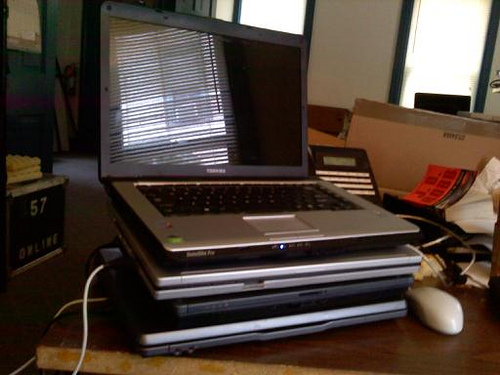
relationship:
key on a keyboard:
[137, 183, 362, 212] [140, 177, 366, 213]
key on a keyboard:
[137, 183, 362, 212] [130, 177, 370, 217]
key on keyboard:
[137, 183, 362, 212] [135, 181, 365, 221]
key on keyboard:
[137, 183, 362, 212] [163, 132, 377, 219]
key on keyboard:
[137, 183, 362, 212] [127, 186, 419, 251]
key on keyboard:
[137, 183, 362, 212] [130, 177, 370, 217]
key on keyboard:
[137, 183, 362, 212] [134, 177, 363, 220]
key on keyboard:
[197, 200, 216, 212] [139, 169, 382, 225]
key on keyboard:
[151, 199, 179, 212] [139, 169, 382, 225]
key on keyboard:
[137, 183, 362, 212] [139, 169, 382, 225]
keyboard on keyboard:
[123, 181, 361, 212] [123, 181, 361, 211]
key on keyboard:
[137, 183, 362, 212] [123, 181, 361, 211]